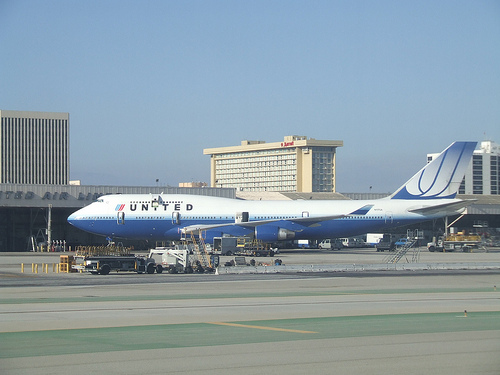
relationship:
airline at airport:
[62, 138, 486, 260] [4, 163, 499, 264]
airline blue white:
[65, 141, 482, 260] [70, 185, 475, 214]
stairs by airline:
[176, 223, 214, 269] [65, 141, 482, 260]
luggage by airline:
[213, 236, 238, 253] [65, 141, 482, 260]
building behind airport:
[196, 135, 340, 194] [4, 163, 499, 264]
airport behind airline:
[4, 163, 499, 264] [65, 141, 482, 260]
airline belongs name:
[65, 141, 482, 260] [130, 203, 192, 212]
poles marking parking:
[17, 259, 66, 278] [6, 267, 123, 292]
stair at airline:
[376, 227, 427, 270] [65, 141, 482, 260]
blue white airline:
[69, 217, 431, 243] [65, 141, 482, 260]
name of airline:
[121, 195, 196, 218] [62, 138, 486, 260]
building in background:
[196, 135, 340, 194] [4, 97, 498, 193]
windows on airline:
[131, 212, 168, 221] [65, 141, 482, 260]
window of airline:
[91, 198, 108, 206] [65, 141, 482, 260]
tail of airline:
[379, 138, 482, 224] [65, 141, 482, 260]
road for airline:
[27, 239, 483, 260] [65, 141, 482, 260]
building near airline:
[196, 135, 340, 194] [65, 141, 482, 260]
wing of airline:
[188, 213, 353, 242] [65, 141, 482, 260]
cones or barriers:
[71, 239, 136, 258] [73, 239, 133, 259]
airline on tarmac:
[65, 141, 482, 260] [70, 242, 498, 289]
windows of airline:
[131, 212, 168, 221] [65, 141, 482, 260]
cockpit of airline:
[90, 196, 109, 206] [65, 141, 482, 260]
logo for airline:
[110, 199, 201, 216] [62, 138, 486, 260]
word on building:
[39, 188, 73, 207] [6, 180, 499, 249]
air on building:
[41, 185, 71, 205] [6, 180, 499, 249]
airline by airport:
[65, 141, 482, 260] [4, 163, 499, 264]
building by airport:
[202, 137, 340, 194] [4, 163, 499, 264]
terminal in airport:
[1, 180, 248, 257] [4, 163, 499, 264]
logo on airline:
[110, 199, 201, 216] [65, 141, 482, 260]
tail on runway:
[379, 138, 482, 224] [308, 239, 495, 271]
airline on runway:
[65, 141, 482, 260] [308, 239, 495, 271]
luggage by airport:
[197, 230, 248, 258] [1, 174, 499, 273]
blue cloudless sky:
[172, 44, 221, 76] [1, 4, 498, 71]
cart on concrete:
[72, 244, 158, 278] [46, 265, 250, 277]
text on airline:
[184, 200, 194, 212] [65, 141, 482, 260]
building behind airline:
[196, 135, 340, 194] [65, 141, 482, 260]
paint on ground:
[345, 313, 375, 342] [0, 281, 498, 358]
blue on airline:
[69, 217, 431, 243] [65, 141, 482, 260]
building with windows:
[1, 106, 73, 184] [10, 125, 44, 148]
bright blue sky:
[108, 71, 230, 140] [1, 4, 498, 71]